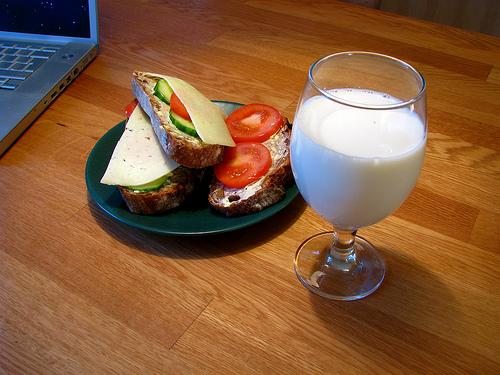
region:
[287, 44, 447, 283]
a glass of milk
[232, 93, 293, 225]
a piece of melba toast with tomato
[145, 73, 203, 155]
cucumber slices on melba toast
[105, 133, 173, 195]
piece of cheese on top of melba toast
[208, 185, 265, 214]
mayonaise on top of toast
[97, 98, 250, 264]
a small green saucer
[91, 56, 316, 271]
small plate with three piece of toast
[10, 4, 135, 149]
a laptop sitting on table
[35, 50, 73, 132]
ports on side of laptop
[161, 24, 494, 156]
wooden kitchen table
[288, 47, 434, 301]
A glass filled with milk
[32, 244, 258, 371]
Light color wooden table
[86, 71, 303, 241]
Green plate with food on it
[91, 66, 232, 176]
Toasts on a plate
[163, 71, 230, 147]
White cheese on a toast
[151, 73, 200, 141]
Pickle slices on a toast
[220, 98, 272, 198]
Ripe tomato slices on a toast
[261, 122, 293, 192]
Butter on a piece of bread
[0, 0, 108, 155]
Silver colored laptop computer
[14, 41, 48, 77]
Keys on a laptop computer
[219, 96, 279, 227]
two slices of tomatoes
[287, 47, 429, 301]
Glass is full of milk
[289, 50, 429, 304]
Glass of milk is to the right of the plate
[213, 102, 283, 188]
The tomatoes are red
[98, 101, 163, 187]
Cheese is on top of the cucumbers and tomatoes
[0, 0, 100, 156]
Laptop is to the left of the plate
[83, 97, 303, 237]
The plate is green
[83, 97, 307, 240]
Plate is between the glass of milk and laptop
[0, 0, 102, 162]
The laptop is gray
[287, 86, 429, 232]
The milk is white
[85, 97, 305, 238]
The plate sits on a wooden surface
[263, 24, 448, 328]
this is a goblet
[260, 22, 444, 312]
this is milk in a goblet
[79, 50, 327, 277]
this is a dinner plate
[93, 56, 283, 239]
this is a sandwich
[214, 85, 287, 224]
these are sliced tomatoes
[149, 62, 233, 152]
this is a slice of cheese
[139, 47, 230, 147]
the cheese is white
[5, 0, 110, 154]
this is a computer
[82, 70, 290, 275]
plate sitting on brown table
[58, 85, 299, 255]
dinner plate is green